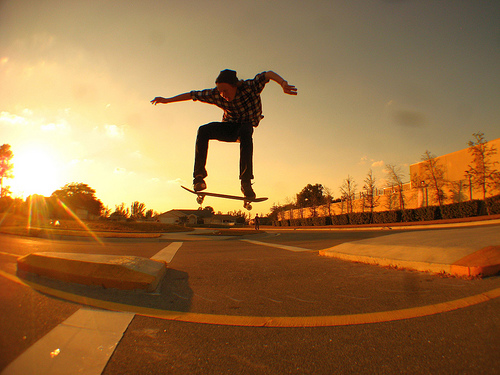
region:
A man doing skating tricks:
[157, 82, 329, 249]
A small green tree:
[463, 118, 493, 214]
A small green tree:
[426, 152, 456, 226]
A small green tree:
[387, 161, 417, 225]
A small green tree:
[347, 176, 384, 224]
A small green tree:
[320, 191, 336, 223]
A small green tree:
[297, 198, 308, 221]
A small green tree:
[131, 195, 176, 233]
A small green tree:
[67, 173, 101, 210]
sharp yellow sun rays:
[26, 176, 101, 263]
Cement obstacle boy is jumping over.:
[16, 251, 166, 292]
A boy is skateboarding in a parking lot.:
[150, 68, 297, 210]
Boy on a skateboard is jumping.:
[150, 68, 298, 212]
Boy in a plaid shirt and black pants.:
[151, 68, 298, 210]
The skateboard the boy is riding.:
[181, 185, 268, 210]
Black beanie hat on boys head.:
[216, 68, 241, 88]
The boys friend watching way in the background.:
[253, 213, 258, 231]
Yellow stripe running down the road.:
[0, 268, 499, 325]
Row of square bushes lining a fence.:
[269, 194, 498, 227]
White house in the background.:
[154, 209, 236, 228]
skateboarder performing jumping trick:
[147, 65, 295, 210]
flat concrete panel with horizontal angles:
[15, 247, 170, 296]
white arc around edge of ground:
[2, 255, 492, 330]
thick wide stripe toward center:
[10, 231, 185, 367]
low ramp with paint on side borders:
[315, 221, 495, 286]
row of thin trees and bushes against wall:
[270, 135, 495, 225]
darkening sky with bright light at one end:
[5, 2, 495, 212]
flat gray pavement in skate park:
[0, 226, 499, 366]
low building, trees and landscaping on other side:
[1, 180, 186, 235]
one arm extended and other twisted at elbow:
[147, 63, 298, 209]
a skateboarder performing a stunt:
[133, 45, 297, 220]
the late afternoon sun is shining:
[15, 134, 96, 241]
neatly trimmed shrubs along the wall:
[269, 205, 490, 225]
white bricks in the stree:
[206, 301, 454, 326]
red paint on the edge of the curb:
[439, 245, 494, 279]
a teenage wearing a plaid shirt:
[140, 66, 319, 196]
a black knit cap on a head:
[215, 62, 239, 82]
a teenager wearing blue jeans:
[157, 53, 288, 185]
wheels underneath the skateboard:
[194, 201, 251, 211]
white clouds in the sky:
[361, 153, 394, 178]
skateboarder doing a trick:
[150, 58, 300, 209]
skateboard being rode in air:
[175, 180, 265, 225]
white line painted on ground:
[0, 305, 135, 370]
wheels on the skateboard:
[235, 200, 250, 210]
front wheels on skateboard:
[190, 190, 205, 205]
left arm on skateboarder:
[258, 64, 308, 107]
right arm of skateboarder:
[146, 86, 212, 110]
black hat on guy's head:
[216, 64, 240, 85]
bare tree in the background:
[459, 132, 498, 216]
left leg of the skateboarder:
[234, 131, 260, 194]